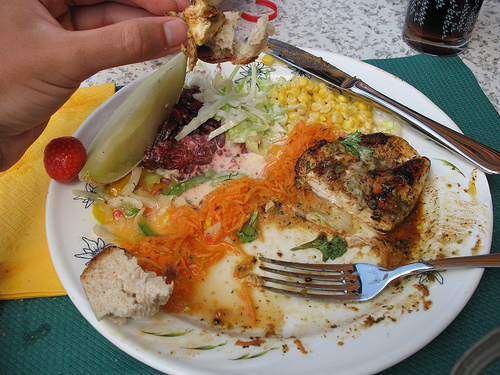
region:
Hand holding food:
[1, 1, 279, 178]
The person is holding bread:
[166, 4, 276, 63]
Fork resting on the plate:
[258, 246, 498, 307]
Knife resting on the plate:
[275, 25, 497, 165]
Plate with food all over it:
[72, 55, 451, 352]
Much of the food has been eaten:
[64, 48, 474, 358]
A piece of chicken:
[298, 123, 433, 225]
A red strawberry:
[40, 123, 93, 189]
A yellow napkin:
[0, 158, 67, 299]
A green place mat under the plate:
[6, 309, 91, 374]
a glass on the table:
[398, 0, 480, 54]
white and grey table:
[301, 7, 396, 55]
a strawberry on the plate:
[42, 138, 77, 180]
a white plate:
[46, 44, 499, 374]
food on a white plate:
[46, 55, 493, 372]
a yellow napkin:
[6, 174, 52, 289]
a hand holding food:
[0, 0, 280, 90]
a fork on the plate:
[257, 251, 488, 297]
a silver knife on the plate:
[260, 30, 495, 175]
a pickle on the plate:
[81, 58, 186, 178]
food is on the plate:
[91, 60, 426, 310]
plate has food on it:
[86, 58, 460, 325]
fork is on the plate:
[257, 255, 499, 303]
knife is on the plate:
[266, 39, 497, 184]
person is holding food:
[160, 5, 277, 70]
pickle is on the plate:
[85, 48, 188, 182]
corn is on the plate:
[267, 75, 372, 135]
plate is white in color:
[62, 223, 471, 370]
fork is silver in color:
[269, 255, 458, 304]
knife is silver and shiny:
[280, 43, 499, 179]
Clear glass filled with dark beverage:
[401, 0, 483, 56]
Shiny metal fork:
[259, 254, 499, 301]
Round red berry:
[44, 136, 85, 182]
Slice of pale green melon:
[78, 49, 185, 182]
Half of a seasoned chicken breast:
[295, 132, 427, 229]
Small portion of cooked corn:
[272, 74, 377, 133]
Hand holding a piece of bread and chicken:
[0, 0, 274, 175]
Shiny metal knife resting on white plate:
[266, 36, 498, 174]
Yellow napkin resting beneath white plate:
[1, 83, 114, 295]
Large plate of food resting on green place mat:
[45, 43, 491, 374]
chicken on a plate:
[297, 126, 419, 235]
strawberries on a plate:
[31, 123, 96, 183]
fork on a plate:
[246, 239, 492, 321]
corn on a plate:
[273, 68, 370, 149]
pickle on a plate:
[56, 53, 206, 181]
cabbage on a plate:
[195, 77, 295, 154]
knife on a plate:
[280, 39, 495, 178]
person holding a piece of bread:
[149, 12, 284, 67]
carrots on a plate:
[166, 166, 285, 244]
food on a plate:
[153, 66, 382, 264]